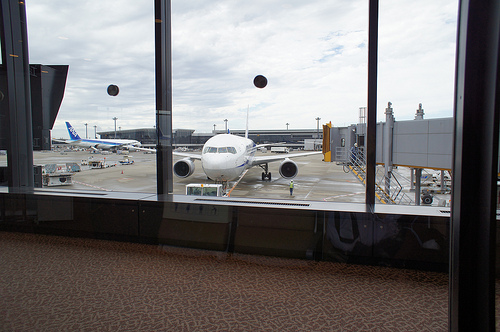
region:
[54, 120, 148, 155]
blue and white plane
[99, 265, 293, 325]
patterned carpet on floor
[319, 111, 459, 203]
loading terminal gate with ladder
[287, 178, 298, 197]
worker on tarmac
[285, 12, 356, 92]
clouds in sky over airport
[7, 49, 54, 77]
lights reflected in windows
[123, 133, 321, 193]
plane pulling into gate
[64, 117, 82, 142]
blue tail fin of plane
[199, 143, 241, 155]
windows for plane cockpit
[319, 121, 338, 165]
yellow trim on gate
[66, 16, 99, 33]
this is the sky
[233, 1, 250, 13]
the sky is blue in color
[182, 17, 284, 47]
the sky has clouds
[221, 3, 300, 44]
the clouds are white in color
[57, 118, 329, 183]
this is an airplane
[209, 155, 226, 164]
the airplane is white in color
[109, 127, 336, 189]
the airplane is on the ground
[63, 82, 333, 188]
the airplane is big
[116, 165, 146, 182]
this is the runway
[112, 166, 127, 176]
this is a road cone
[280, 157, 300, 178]
the left engine of an airplane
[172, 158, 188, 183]
the right engine of an airplane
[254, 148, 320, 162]
the left wing of an airplane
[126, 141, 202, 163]
the right wing of an airplane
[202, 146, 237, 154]
the cockpit windows of an airplane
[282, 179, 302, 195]
a person standing on the airport tarmac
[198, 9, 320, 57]
clouds in the sky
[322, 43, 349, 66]
blue sky visible through the clouds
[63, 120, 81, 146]
the tail section of an airplane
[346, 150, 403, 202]
metal stairs painted grey and yellow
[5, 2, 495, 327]
Exterior of airport, viewed through interior window.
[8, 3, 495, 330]
Overcast, daytime view of airport, as seen through glass windows.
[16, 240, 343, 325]
Brown, floor surface, slanting.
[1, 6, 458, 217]
Glass plate window sections, partitioned with metal.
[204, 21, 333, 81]
Heavy cloud banks, in lightly blue sky.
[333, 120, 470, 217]
Airport gate walkway, with attached staircase.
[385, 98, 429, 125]
Two workers, topping walkway.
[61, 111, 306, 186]
Two planes, atop tarmac.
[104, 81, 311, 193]
Black discs, on glass surface, interior.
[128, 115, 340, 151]
Low, wide grey building and tall lights, in distance, beyond planes.